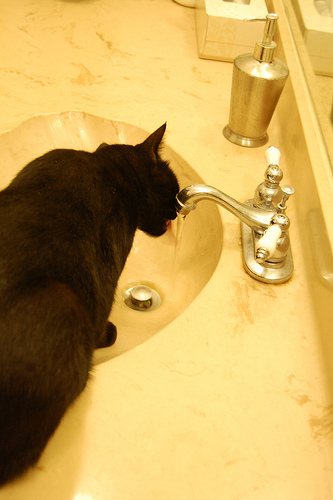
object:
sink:
[16, 105, 250, 342]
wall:
[251, 70, 296, 93]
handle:
[264, 145, 283, 189]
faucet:
[174, 146, 288, 263]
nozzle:
[244, 15, 267, 21]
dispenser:
[223, 13, 290, 147]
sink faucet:
[173, 146, 295, 285]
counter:
[11, 12, 177, 100]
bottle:
[222, 12, 289, 148]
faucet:
[175, 183, 275, 234]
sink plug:
[130, 285, 152, 308]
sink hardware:
[173, 147, 294, 285]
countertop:
[0, 0, 333, 497]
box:
[194, 0, 268, 62]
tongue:
[165, 220, 173, 234]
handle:
[254, 223, 280, 263]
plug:
[130, 284, 153, 307]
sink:
[0, 108, 223, 370]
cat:
[0, 124, 179, 487]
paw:
[95, 319, 117, 348]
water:
[171, 210, 190, 294]